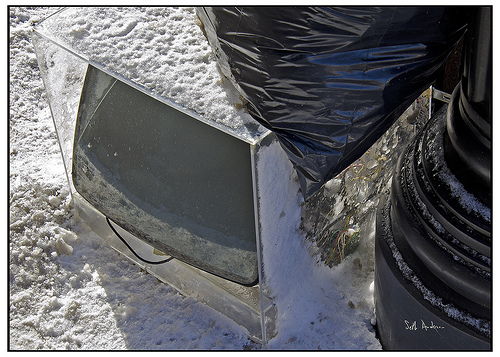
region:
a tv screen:
[70, 95, 253, 271]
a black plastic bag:
[240, 23, 356, 112]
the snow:
[34, 264, 84, 329]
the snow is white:
[19, 272, 124, 339]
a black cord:
[132, 243, 162, 269]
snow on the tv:
[131, 27, 198, 79]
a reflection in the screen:
[81, 150, 152, 212]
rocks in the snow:
[21, 220, 76, 269]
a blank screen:
[92, 121, 219, 214]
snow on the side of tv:
[263, 173, 310, 268]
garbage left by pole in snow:
[20, 18, 486, 339]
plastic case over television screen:
[30, 10, 335, 343]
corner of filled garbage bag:
[197, 10, 483, 200]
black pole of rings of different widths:
[365, 45, 485, 345]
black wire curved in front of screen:
[102, 200, 177, 266]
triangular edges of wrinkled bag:
[200, 10, 485, 196]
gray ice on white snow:
[10, 127, 70, 342]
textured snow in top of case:
[35, 10, 267, 145]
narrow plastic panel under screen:
[65, 190, 275, 335]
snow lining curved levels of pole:
[430, 167, 490, 342]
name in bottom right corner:
[391, 313, 459, 341]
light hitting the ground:
[25, 280, 83, 328]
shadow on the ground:
[98, 293, 157, 343]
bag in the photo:
[265, 41, 398, 125]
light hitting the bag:
[278, 28, 358, 82]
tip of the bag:
[270, 130, 376, 224]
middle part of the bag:
[300, 17, 387, 73]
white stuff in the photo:
[96, 18, 185, 70]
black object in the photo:
[426, 92, 488, 212]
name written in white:
[385, 310, 451, 349]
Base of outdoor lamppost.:
[375, 5, 489, 350]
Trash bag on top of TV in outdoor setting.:
[195, 4, 460, 192]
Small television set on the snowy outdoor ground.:
[30, 5, 365, 340]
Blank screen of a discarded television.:
[70, 63, 264, 285]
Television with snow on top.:
[34, 5, 364, 337]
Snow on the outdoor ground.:
[11, 174, 239, 352]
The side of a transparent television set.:
[255, 133, 430, 275]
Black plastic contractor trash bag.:
[195, 7, 466, 192]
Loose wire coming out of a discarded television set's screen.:
[104, 211, 181, 271]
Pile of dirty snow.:
[10, 170, 75, 292]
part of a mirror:
[167, 137, 227, 188]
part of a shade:
[99, 281, 134, 329]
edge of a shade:
[96, 280, 118, 315]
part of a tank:
[402, 221, 435, 303]